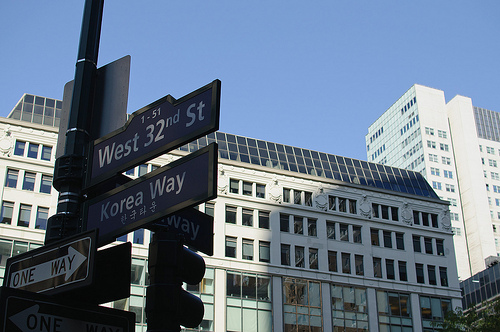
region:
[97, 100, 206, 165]
the text is white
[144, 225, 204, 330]
a set of traffic lights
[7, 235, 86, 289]
a one way sign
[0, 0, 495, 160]
no clouds in the sky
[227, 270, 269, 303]
windows on the building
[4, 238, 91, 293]
sign is black and white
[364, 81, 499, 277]
a tall white building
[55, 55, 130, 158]
back of a sign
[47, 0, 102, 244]
pole is dark metal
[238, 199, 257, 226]
This is a window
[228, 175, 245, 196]
This is a window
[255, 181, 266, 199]
This is a window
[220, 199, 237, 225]
This is a window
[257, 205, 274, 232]
This is a window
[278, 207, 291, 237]
This is a window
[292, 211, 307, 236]
This is a window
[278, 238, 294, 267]
This is a window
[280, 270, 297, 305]
This is a window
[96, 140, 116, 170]
white letter on sign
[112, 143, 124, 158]
white letter on sign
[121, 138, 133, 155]
white letter on sign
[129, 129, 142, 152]
white letter on sign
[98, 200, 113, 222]
white letter on sign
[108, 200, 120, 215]
white letter on sign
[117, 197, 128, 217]
white letter on sign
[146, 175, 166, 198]
white letter on sign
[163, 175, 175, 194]
white letter on sign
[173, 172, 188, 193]
white letter on sign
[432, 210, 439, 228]
glass window on building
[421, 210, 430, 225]
glass window on building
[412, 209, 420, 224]
glass window on building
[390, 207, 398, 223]
glass window on building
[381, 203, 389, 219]
glass window on building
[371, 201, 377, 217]
glass window on building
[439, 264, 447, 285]
glass window on building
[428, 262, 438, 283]
glass window on building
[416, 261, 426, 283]
glass window on building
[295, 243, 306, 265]
glass window on building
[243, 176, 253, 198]
This is a window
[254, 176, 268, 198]
This is a window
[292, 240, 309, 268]
This is a window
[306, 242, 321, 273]
This is a window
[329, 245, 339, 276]
This is a window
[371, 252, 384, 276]
This is a window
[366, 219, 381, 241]
This is a window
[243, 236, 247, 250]
a window on the building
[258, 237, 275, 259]
a window on the building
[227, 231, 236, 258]
a window on the building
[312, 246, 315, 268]
a window on the building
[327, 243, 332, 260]
a window on the building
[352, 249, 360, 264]
a window on the building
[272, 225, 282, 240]
a window on the building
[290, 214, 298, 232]
a window on the building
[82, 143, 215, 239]
black sign is rectangular